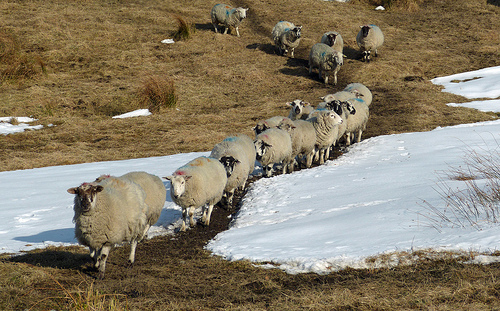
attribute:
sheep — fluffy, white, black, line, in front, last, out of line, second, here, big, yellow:
[186, 161, 225, 187]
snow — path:
[472, 75, 487, 91]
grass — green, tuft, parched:
[7, 41, 86, 98]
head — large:
[293, 79, 345, 133]